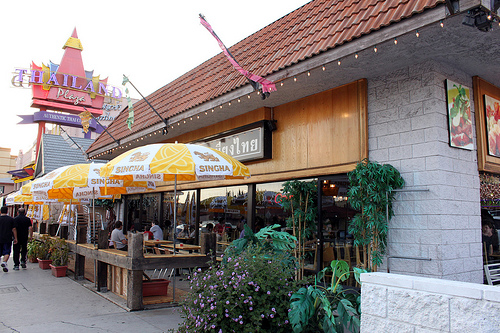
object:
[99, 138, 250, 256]
umbrella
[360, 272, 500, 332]
wall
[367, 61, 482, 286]
wall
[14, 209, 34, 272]
man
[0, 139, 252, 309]
resturant